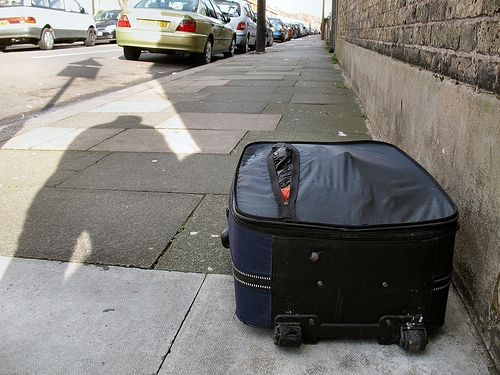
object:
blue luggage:
[219, 139, 461, 353]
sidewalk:
[0, 34, 500, 375]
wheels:
[222, 37, 236, 58]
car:
[211, 0, 258, 55]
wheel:
[402, 325, 428, 353]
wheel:
[277, 322, 302, 348]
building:
[329, 0, 500, 375]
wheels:
[281, 36, 286, 42]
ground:
[0, 40, 497, 375]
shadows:
[0, 114, 182, 317]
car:
[115, 0, 235, 67]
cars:
[298, 23, 308, 37]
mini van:
[0, 0, 99, 51]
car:
[284, 21, 295, 40]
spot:
[102, 308, 116, 313]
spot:
[98, 261, 110, 270]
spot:
[330, 355, 362, 369]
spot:
[304, 358, 323, 374]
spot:
[113, 137, 126, 143]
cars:
[256, 20, 274, 48]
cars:
[0, 0, 98, 50]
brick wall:
[330, 0, 498, 90]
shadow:
[42, 56, 105, 111]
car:
[91, 8, 121, 40]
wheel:
[37, 28, 55, 50]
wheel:
[83, 27, 96, 47]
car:
[267, 17, 290, 42]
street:
[0, 39, 225, 118]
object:
[280, 184, 290, 203]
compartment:
[236, 140, 454, 226]